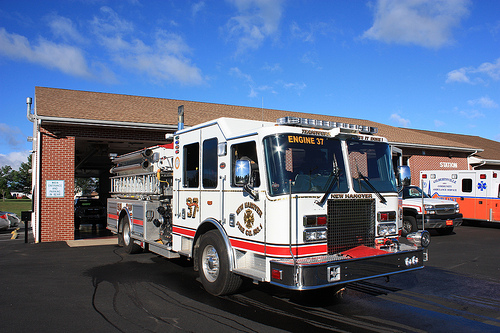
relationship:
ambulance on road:
[105, 101, 432, 297] [4, 208, 499, 331]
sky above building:
[1, 2, 499, 161] [31, 84, 480, 261]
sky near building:
[1, 2, 499, 161] [31, 84, 480, 261]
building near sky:
[31, 84, 480, 261] [1, 2, 499, 161]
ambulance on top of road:
[105, 101, 432, 297] [4, 208, 499, 331]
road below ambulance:
[4, 208, 499, 331] [105, 101, 432, 297]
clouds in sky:
[14, 24, 241, 83] [1, 2, 499, 161]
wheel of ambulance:
[103, 200, 147, 250] [105, 101, 432, 297]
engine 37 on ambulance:
[277, 132, 337, 153] [105, 101, 432, 297]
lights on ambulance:
[267, 210, 437, 243] [105, 101, 432, 297]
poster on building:
[47, 180, 63, 197] [29, 77, 467, 208]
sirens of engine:
[278, 114, 378, 134] [105, 101, 421, 296]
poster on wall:
[47, 180, 63, 197] [42, 133, 74, 240]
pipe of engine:
[177, 99, 187, 131] [105, 101, 421, 296]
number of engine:
[316, 137, 326, 144] [105, 101, 421, 296]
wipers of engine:
[315, 171, 336, 204] [105, 101, 421, 296]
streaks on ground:
[270, 294, 490, 330] [3, 290, 496, 330]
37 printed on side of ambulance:
[179, 199, 198, 219] [105, 101, 432, 297]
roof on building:
[38, 85, 482, 152] [39, 141, 474, 241]